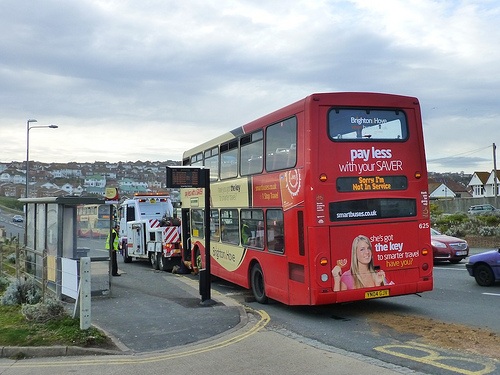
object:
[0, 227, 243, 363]
station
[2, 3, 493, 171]
sky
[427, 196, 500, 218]
fence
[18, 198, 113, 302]
bus stop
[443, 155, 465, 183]
ground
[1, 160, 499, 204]
buildings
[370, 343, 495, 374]
letter b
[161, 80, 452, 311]
bus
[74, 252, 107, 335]
sign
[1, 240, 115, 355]
grass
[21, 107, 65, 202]
overhead light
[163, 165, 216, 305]
electronic sign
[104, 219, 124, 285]
man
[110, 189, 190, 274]
truck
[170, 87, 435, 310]
bus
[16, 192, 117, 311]
busstop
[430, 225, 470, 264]
car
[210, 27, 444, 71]
sky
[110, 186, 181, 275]
tow truck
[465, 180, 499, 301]
car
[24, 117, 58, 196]
lamp post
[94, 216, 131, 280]
worker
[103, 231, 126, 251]
vest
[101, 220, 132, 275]
man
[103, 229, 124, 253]
safety attire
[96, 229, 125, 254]
vest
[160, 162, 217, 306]
bus stop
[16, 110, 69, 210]
lamp post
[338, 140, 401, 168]
lettering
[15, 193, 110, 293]
bus stop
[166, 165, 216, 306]
sign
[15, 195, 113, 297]
shelter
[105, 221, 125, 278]
man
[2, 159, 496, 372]
street